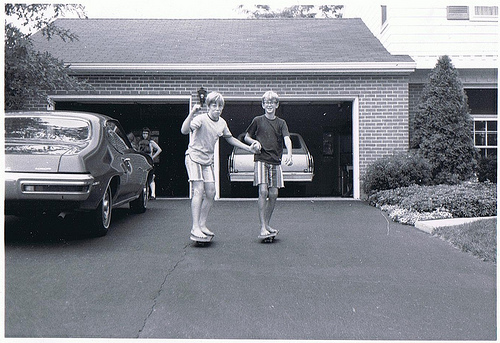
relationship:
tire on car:
[82, 181, 114, 240] [8, 100, 155, 242]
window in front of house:
[470, 117, 498, 146] [227, 7, 499, 196]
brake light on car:
[26, 181, 93, 198] [4, 98, 160, 257]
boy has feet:
[244, 89, 293, 236] [260, 225, 277, 235]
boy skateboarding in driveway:
[179, 90, 260, 239] [152, 197, 422, 341]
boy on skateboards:
[179, 90, 260, 239] [190, 236, 280, 246]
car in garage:
[228, 132, 315, 196] [210, 91, 412, 206]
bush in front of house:
[411, 52, 479, 179] [7, 19, 498, 193]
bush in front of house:
[362, 150, 431, 189] [7, 19, 498, 193]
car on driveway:
[0, 110, 156, 237] [2, 193, 497, 338]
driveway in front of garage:
[2, 193, 497, 338] [48, 96, 356, 196]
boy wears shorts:
[177, 89, 230, 255] [180, 149, 219, 191]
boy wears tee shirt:
[177, 89, 230, 255] [178, 108, 238, 168]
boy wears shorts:
[244, 85, 296, 248] [244, 156, 286, 196]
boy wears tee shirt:
[177, 89, 230, 255] [240, 108, 295, 169]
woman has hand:
[136, 124, 166, 200] [150, 152, 156, 160]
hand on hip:
[150, 152, 156, 160] [151, 152, 156, 163]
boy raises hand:
[244, 89, 293, 236] [245, 144, 257, 156]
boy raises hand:
[244, 89, 293, 236] [190, 100, 207, 114]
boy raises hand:
[179, 90, 260, 239] [282, 154, 296, 169]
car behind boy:
[282, 147, 303, 182] [246, 90, 283, 237]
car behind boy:
[282, 147, 303, 182] [175, 80, 222, 242]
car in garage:
[282, 147, 303, 182] [51, 97, 388, 192]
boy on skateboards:
[179, 90, 260, 239] [188, 228, 277, 248]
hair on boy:
[206, 88, 223, 109] [177, 91, 252, 242]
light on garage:
[195, 86, 206, 104] [11, 17, 418, 199]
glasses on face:
[190, 92, 258, 119] [240, 79, 292, 116]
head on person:
[204, 92, 222, 120] [177, 85, 247, 230]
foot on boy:
[188, 227, 206, 238] [179, 90, 260, 239]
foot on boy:
[199, 222, 214, 237] [179, 90, 260, 239]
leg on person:
[240, 180, 287, 248] [211, 60, 326, 227]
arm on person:
[213, 118, 255, 157] [176, 81, 260, 250]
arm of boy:
[244, 131, 261, 148] [244, 89, 293, 236]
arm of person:
[178, 101, 199, 135] [178, 89, 253, 236]